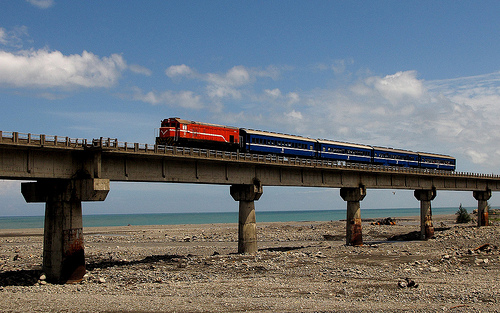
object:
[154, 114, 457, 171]
train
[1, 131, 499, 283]
bridge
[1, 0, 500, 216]
sky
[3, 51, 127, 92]
clouds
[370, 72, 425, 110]
clouds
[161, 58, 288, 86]
clouds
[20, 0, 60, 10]
clouds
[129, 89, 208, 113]
clouds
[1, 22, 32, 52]
clouds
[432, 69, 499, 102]
clouds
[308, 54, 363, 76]
clouds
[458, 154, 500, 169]
clouds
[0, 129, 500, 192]
train tracks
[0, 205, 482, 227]
ocean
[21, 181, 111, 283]
concrete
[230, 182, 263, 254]
concrete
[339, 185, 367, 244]
concrete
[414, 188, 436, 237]
concrete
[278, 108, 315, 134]
clouds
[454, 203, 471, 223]
shrub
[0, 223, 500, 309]
rocky area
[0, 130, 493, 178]
stripe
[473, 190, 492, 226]
concrete